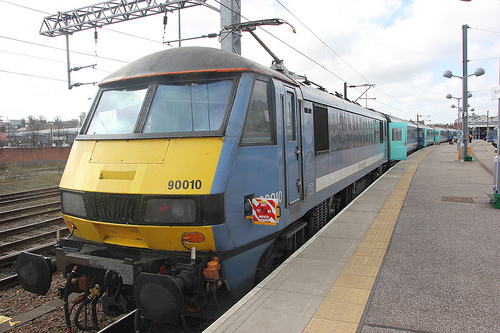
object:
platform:
[202, 139, 500, 332]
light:
[440, 69, 455, 80]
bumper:
[135, 271, 181, 332]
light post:
[455, 99, 461, 149]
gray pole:
[460, 24, 469, 161]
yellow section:
[58, 137, 221, 195]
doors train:
[434, 129, 442, 146]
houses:
[4, 128, 81, 147]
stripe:
[314, 150, 383, 195]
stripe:
[404, 140, 421, 148]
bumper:
[14, 250, 53, 296]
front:
[15, 47, 250, 332]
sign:
[248, 198, 281, 228]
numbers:
[194, 180, 201, 191]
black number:
[166, 180, 173, 190]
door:
[280, 83, 305, 209]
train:
[14, 44, 466, 332]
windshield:
[81, 75, 229, 135]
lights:
[136, 196, 205, 225]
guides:
[0, 0, 174, 49]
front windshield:
[138, 78, 241, 134]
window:
[239, 77, 274, 146]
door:
[388, 122, 407, 161]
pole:
[218, 0, 240, 55]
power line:
[0, 33, 129, 65]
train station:
[197, 139, 497, 333]